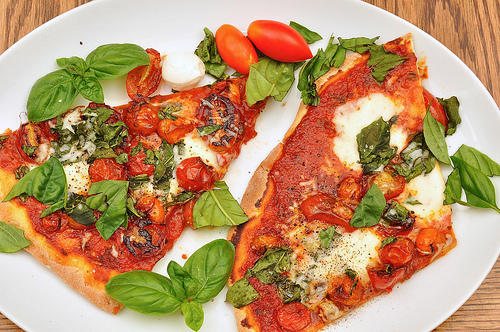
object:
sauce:
[9, 75, 259, 277]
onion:
[194, 92, 249, 146]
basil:
[23, 40, 152, 128]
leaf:
[74, 73, 104, 103]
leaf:
[178, 300, 203, 330]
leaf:
[191, 180, 250, 228]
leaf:
[182, 237, 236, 301]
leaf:
[420, 99, 455, 171]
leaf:
[86, 44, 148, 77]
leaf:
[103, 268, 182, 318]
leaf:
[451, 142, 486, 207]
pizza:
[2, 68, 273, 317]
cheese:
[399, 163, 446, 215]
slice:
[234, 31, 455, 332]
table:
[31, 3, 498, 327]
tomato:
[173, 156, 210, 198]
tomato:
[119, 101, 160, 140]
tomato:
[88, 153, 121, 185]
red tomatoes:
[213, 22, 257, 74]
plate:
[2, 1, 499, 328]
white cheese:
[334, 96, 402, 137]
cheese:
[289, 93, 443, 293]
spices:
[260, 169, 373, 300]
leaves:
[178, 239, 232, 303]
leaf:
[26, 67, 76, 122]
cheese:
[155, 49, 210, 91]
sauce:
[293, 130, 325, 159]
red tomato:
[215, 21, 256, 81]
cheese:
[58, 145, 89, 184]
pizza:
[10, 24, 467, 315]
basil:
[351, 186, 385, 226]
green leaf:
[0, 222, 20, 262]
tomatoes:
[126, 153, 156, 179]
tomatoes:
[298, 190, 355, 227]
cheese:
[277, 217, 391, 309]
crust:
[1, 202, 84, 296]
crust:
[223, 144, 268, 282]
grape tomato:
[124, 42, 161, 106]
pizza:
[253, 42, 458, 305]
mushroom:
[18, 118, 41, 155]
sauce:
[283, 164, 301, 182]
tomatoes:
[244, 16, 318, 64]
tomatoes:
[178, 158, 213, 191]